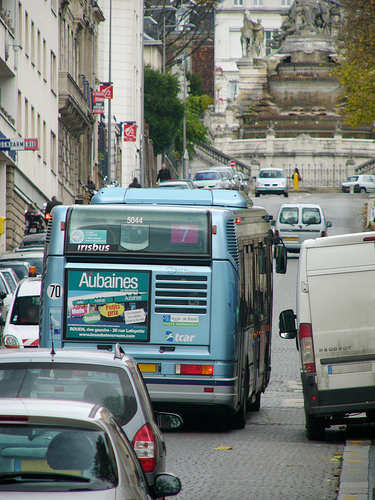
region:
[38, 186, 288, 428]
Bus moving in traffic.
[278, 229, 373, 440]
White van parked on the side walk.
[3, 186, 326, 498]
Vehicles moving on a busy street.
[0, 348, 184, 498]
Two cars behind the bus.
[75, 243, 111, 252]
Irisbus sign on the blue bus.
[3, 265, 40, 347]
City worker driving a white car.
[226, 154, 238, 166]
Red stop traffic sign.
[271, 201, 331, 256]
White van moving in front of blue bus.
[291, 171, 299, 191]
Yellow pole on the side of street.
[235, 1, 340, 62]
Statues on a monument.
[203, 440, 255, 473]
yellow object in street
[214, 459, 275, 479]
grooves on cobble stone street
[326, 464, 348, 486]
edge of sidewalk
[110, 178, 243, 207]
neon blue color on bus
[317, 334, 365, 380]
dirt on white van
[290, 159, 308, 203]
yellow and black fire hydrant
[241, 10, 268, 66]
large statue on base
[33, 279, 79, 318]
large black words on bus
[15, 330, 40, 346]
white and red paint on small bus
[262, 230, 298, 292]
large mirror on bus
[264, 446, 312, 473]
part of a road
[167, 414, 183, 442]
part of a side mirror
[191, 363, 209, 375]
part of an indicator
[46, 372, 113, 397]
rear window of a car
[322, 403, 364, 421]
bottom edge of a car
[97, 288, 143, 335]
part of a banner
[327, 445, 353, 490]
edge of a road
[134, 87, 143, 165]
part of a post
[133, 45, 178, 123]
part of a tree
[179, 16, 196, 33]
part of a street lamp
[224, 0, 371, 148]
A large fountain at the end of the street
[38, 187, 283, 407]
public transportation bus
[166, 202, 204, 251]
Indicates route number 7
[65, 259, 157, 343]
An advertisement posted on rear of bus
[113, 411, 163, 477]
rear light of an automobile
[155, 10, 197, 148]
tall steel street light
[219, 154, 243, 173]
a Do Not Enter sign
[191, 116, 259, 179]
a concrete stairway to fountain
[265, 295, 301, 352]
a side view mirror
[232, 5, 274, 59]
a sculpture of a man standing near a horse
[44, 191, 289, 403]
Large light blue bus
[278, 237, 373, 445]
Large white van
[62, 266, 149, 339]
Green sign on the back of bus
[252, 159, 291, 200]
Silver car coming down the street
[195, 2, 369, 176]
Large stone statue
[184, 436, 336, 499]
Gray cobblestone street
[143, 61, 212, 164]
Small green bushes behind buildings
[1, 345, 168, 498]
Two cars driving behind the bus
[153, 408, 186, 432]
Car's side mirror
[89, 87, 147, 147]
Red street signs above the street